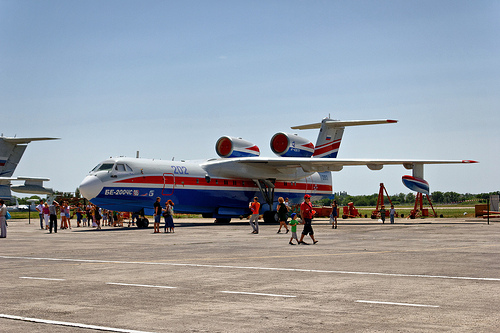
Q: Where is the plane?
A: The runway.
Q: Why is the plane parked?
A: Being loaded.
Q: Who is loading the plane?
A: A group of people.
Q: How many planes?
A: 2.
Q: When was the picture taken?
A: Daytime.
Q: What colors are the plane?
A: Red white and bule.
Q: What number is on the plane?
A: 202.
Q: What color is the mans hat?
A: Red.